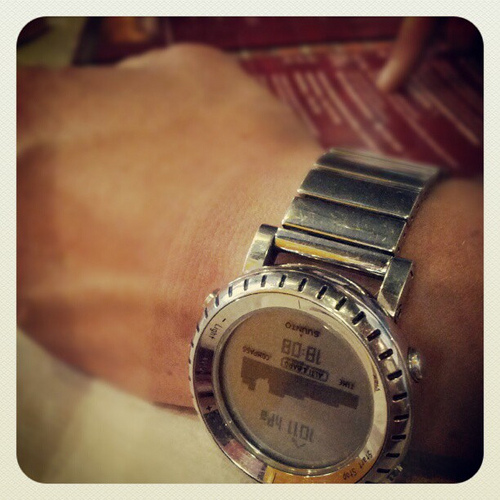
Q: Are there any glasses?
A: No, there are no glasses.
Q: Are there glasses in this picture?
A: No, there are no glasses.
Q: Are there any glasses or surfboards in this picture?
A: No, there are no glasses or surfboards.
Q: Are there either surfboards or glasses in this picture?
A: No, there are no glasses or surfboards.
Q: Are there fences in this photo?
A: No, there are no fences.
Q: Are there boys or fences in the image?
A: No, there are no fences or boys.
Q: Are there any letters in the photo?
A: Yes, there are letters.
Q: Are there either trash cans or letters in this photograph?
A: Yes, there are letters.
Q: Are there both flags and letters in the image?
A: No, there are letters but no flags.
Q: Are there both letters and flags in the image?
A: No, there are letters but no flags.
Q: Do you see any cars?
A: No, there are no cars.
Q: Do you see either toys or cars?
A: No, there are no cars or toys.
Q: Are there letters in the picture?
A: Yes, there are letters.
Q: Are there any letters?
A: Yes, there are letters.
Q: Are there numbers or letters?
A: Yes, there are letters.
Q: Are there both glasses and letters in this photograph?
A: No, there are letters but no glasses.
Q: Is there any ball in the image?
A: No, there are no balls.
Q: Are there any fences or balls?
A: No, there are no balls or fences.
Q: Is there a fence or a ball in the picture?
A: No, there are no balls or fences.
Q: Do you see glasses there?
A: No, there are no glasses.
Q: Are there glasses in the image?
A: No, there are no glasses.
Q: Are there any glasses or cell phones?
A: No, there are no glasses or cell phones.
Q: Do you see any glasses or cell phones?
A: No, there are no glasses or cell phones.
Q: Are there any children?
A: No, there are no children.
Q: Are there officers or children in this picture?
A: No, there are no children or officers.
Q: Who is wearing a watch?
A: The man is wearing a watch.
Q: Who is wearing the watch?
A: The man is wearing a watch.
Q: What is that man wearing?
A: The man is wearing a watch.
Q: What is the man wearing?
A: The man is wearing a watch.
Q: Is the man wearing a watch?
A: Yes, the man is wearing a watch.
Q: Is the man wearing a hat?
A: No, the man is wearing a watch.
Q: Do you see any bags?
A: No, there are no bags.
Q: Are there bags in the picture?
A: No, there are no bags.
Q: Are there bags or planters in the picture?
A: No, there are no bags or planters.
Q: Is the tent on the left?
A: No, the tent is on the right of the image.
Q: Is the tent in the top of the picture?
A: No, the tent is in the bottom of the image.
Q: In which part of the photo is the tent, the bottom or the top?
A: The tent is in the bottom of the image.